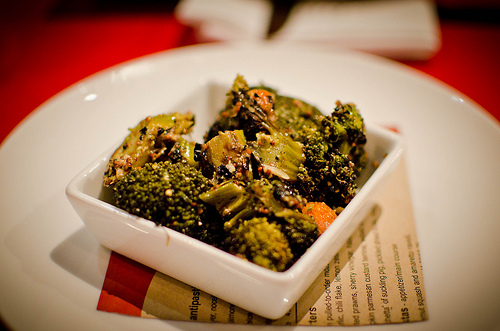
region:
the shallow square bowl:
[66, 75, 403, 318]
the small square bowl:
[67, 75, 407, 320]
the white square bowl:
[67, 75, 407, 320]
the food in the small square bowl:
[66, 72, 403, 317]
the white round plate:
[0, 42, 497, 329]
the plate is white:
[0, 41, 498, 329]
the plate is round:
[0, 40, 498, 327]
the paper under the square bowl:
[95, 123, 429, 325]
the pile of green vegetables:
[102, 72, 365, 271]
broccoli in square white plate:
[98, 67, 374, 279]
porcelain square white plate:
[61, 64, 411, 321]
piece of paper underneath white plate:
[93, 117, 431, 329]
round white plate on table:
[2, 32, 499, 329]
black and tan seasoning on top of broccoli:
[130, 124, 169, 160]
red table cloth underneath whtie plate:
[1, 10, 497, 152]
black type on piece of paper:
[185, 199, 433, 328]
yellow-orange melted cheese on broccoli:
[295, 192, 339, 234]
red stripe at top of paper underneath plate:
[91, 243, 163, 323]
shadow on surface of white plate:
[39, 221, 109, 291]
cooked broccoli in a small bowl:
[111, 70, 368, 262]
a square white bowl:
[65, 73, 405, 321]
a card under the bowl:
[96, 122, 437, 327]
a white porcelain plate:
[0, 48, 499, 328]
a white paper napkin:
[177, 0, 439, 60]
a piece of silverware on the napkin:
[258, 3, 296, 37]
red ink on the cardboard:
[98, 248, 156, 319]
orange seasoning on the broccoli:
[300, 198, 334, 231]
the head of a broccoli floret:
[114, 158, 208, 228]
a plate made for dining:
[4, 37, 498, 325]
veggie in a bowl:
[112, 152, 212, 236]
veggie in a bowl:
[230, 191, 272, 265]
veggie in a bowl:
[308, 98, 359, 197]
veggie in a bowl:
[217, 115, 258, 189]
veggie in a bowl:
[225, 78, 275, 133]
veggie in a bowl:
[245, 109, 310, 186]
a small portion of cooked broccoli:
[111, 73, 362, 268]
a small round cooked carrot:
[300, 195, 337, 233]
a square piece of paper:
[94, 120, 429, 325]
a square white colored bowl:
[65, 74, 406, 321]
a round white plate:
[2, 45, 499, 328]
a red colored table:
[2, 7, 499, 144]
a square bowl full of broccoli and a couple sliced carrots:
[63, 72, 405, 321]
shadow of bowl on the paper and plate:
[51, 202, 387, 329]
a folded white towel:
[177, 1, 442, 58]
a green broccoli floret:
[108, 156, 218, 248]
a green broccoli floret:
[245, 123, 360, 206]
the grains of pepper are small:
[248, 196, 273, 221]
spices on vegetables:
[100, 140, 142, 188]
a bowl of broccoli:
[48, 62, 422, 293]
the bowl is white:
[42, 69, 429, 308]